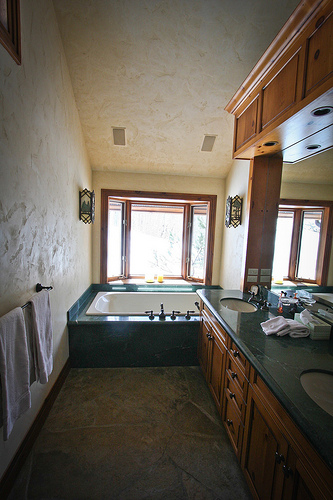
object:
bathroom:
[0, 0, 333, 499]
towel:
[300, 309, 320, 326]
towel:
[260, 316, 311, 339]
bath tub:
[86, 291, 201, 315]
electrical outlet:
[247, 268, 258, 282]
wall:
[267, 160, 273, 237]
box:
[294, 313, 332, 341]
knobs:
[274, 452, 284, 464]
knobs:
[282, 465, 293, 480]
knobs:
[231, 372, 237, 379]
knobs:
[230, 392, 235, 400]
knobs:
[227, 419, 233, 427]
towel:
[24, 288, 53, 384]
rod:
[21, 283, 53, 310]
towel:
[0, 306, 31, 442]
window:
[101, 189, 210, 285]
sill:
[108, 277, 204, 286]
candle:
[145, 269, 155, 282]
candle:
[158, 276, 164, 283]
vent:
[314, 109, 331, 116]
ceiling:
[145, 29, 242, 86]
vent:
[265, 142, 275, 146]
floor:
[0, 366, 256, 500]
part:
[84, 365, 179, 449]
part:
[14, 314, 25, 400]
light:
[79, 188, 95, 225]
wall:
[0, 0, 98, 435]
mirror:
[272, 211, 323, 280]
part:
[299, 189, 318, 248]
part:
[133, 211, 176, 253]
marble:
[67, 284, 203, 368]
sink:
[220, 298, 258, 312]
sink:
[300, 370, 333, 415]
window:
[271, 204, 329, 287]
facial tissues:
[300, 308, 321, 325]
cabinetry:
[223, 0, 333, 165]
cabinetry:
[197, 299, 229, 417]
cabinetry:
[240, 365, 333, 500]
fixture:
[36, 283, 53, 293]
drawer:
[228, 337, 251, 380]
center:
[196, 285, 333, 500]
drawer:
[226, 350, 249, 404]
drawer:
[225, 368, 246, 425]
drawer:
[225, 397, 241, 447]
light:
[225, 195, 243, 229]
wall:
[226, 167, 247, 281]